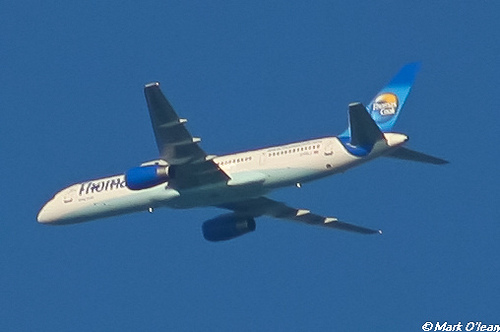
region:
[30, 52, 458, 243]
blue and white ariplane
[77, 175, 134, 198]
lettering on the plane's side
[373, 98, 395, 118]
white lettering on plane's tail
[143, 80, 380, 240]
wings of the airplane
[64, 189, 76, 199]
door on the front of the plane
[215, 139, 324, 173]
row of windows on side of plane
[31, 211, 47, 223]
white nose of the airplane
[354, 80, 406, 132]
blue tail fin on the plane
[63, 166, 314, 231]
light blue underside of airplane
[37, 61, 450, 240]
A large white and blue plane.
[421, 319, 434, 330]
A white copyright symbol.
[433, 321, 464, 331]
A white Mark name on the bottom.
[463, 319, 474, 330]
A white O after Mark.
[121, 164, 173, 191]
The closest blue and grey engine.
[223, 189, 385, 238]
The furthest dark wing.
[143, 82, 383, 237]
The middle long wings of a plane.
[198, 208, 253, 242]
The furthest blue and grey engine.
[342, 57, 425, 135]
A blue tail end of a plane with a circle and writing in it.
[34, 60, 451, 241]
A large mostly white airplane.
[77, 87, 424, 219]
a plane in the sky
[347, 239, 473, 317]
A blue sky background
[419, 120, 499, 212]
A blue sky background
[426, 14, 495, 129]
A blue sky background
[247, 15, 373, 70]
A blue sky background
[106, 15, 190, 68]
A blue sky background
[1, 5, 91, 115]
A blue sky background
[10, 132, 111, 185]
A blue sky background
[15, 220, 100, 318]
A blue sky background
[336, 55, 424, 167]
blue tail fin of jumbo jet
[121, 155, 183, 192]
blue engine of jumbo jet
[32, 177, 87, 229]
white and blue cockpit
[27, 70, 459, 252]
blue jumbo jet flying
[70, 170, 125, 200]
blue letters on side of plane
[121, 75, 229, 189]
wing and engine of jumbo jet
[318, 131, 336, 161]
rear escape hatch of jumbo jet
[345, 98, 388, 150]
blue tail fin of jumbo jet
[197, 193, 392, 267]
right wing and blue engine of jumbo jet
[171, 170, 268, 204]
blue underbelly of jumbo jet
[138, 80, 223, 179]
wing on the plane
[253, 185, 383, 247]
wing on the plane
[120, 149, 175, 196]
engine on the plane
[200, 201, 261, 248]
engine on the plane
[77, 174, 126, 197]
words on the plane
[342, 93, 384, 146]
tail on the plane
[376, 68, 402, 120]
tail on the plane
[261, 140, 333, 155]
windows on the plane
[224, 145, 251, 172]
windows on the plane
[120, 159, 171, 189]
engine on the white airplane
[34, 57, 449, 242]
white airplane flying in sky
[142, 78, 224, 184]
large left winf of white airplane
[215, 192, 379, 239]
large left wing of white airplane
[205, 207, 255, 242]
small blue right propeller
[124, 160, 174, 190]
small blue left propeller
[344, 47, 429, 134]
dark and light blue empennage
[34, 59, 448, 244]
big blue and white airplane in blue clear sky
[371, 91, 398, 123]
picture of person in airplane tail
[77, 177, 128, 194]
blue letters on white airplane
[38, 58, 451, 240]
the airplane is flying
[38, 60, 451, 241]
the airplane is in motion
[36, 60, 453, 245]
the airplane is moving